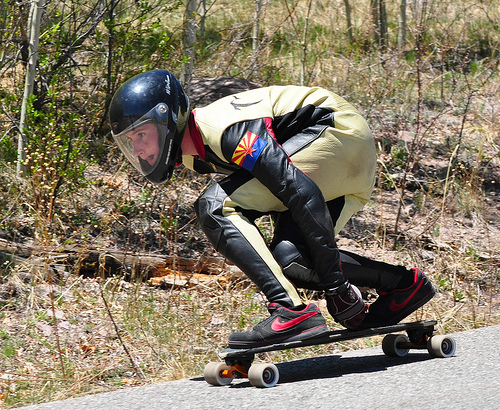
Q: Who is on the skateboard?
A: A boy.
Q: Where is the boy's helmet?
A: On his head.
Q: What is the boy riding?
A: A skateboard.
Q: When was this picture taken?
A: During the day.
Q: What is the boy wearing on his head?
A: A helmet.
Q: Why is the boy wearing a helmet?
A: To protect his head.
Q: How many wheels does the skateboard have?
A: Four.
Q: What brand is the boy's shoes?
A: Nike.